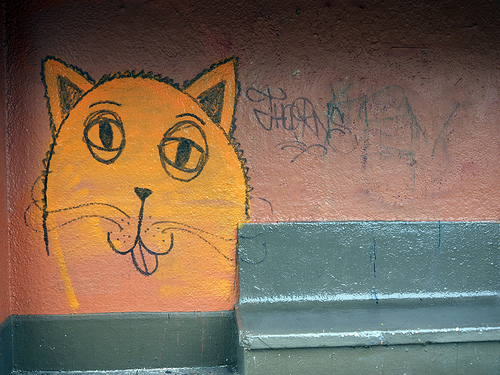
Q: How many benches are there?
A: 1.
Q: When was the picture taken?
A: In the day time.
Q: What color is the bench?
A: Gray.